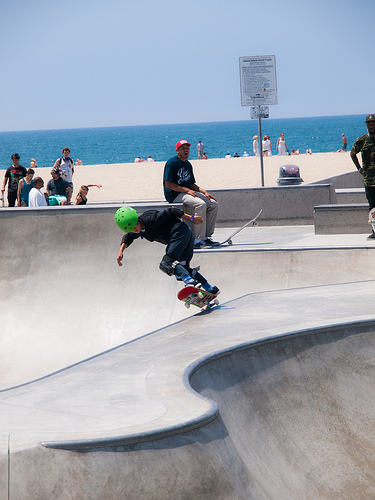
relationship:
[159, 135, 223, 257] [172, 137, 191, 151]
man wearing hat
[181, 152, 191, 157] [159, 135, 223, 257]
mouth of man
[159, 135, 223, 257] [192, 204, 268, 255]
man on skateboard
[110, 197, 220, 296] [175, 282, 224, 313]
child riding skateboard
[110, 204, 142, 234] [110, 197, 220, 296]
helmet on child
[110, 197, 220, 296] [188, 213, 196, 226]
child wearing watch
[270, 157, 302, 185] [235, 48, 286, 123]
trash can next to sign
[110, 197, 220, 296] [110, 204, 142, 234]
child wearing helmet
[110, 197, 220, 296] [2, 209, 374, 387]
child on ramp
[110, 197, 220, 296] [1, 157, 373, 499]
child at park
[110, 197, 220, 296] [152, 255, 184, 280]
child wearing guards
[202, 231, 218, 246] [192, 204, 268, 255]
foot on skateboard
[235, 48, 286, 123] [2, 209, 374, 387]
sign next to ramp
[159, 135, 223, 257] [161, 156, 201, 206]
man wearing shirt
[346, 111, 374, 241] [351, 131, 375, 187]
man wearing shirt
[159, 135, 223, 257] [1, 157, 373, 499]
man at park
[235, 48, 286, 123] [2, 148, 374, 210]
sign on beach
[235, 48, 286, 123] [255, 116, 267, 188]
sign on pole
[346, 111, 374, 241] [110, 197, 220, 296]
man watching child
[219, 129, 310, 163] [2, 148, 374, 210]
crowd at beach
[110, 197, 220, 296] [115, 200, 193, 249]
child wearing shirt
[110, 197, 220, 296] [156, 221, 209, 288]
child wearing pants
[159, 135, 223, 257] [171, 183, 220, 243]
man wearing pants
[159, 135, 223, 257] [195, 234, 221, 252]
man wearing shoes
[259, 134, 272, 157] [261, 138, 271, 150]
woman wearing shirt